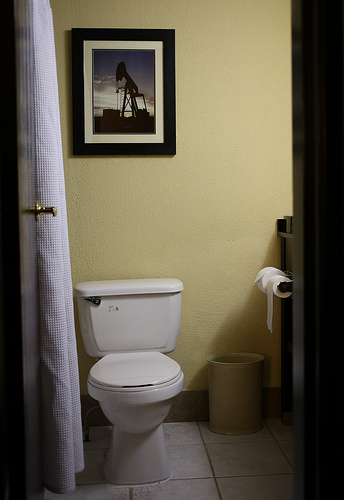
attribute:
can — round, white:
[207, 350, 260, 433]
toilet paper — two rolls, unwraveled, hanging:
[269, 276, 292, 302]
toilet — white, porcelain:
[77, 265, 193, 440]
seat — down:
[93, 361, 181, 385]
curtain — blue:
[31, 21, 64, 200]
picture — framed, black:
[58, 23, 186, 158]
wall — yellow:
[213, 54, 254, 117]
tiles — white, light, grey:
[213, 434, 273, 489]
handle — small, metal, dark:
[85, 294, 109, 311]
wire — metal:
[83, 402, 103, 441]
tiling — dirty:
[193, 446, 277, 493]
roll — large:
[257, 261, 271, 285]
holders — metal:
[282, 275, 291, 295]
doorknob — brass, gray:
[22, 199, 61, 222]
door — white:
[5, 30, 40, 499]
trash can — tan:
[202, 354, 250, 394]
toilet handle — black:
[89, 297, 103, 307]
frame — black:
[78, 29, 169, 44]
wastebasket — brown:
[209, 397, 268, 431]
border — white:
[122, 38, 165, 51]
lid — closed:
[115, 379, 159, 392]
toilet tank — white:
[76, 275, 188, 352]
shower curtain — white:
[17, 21, 62, 168]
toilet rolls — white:
[250, 266, 292, 293]